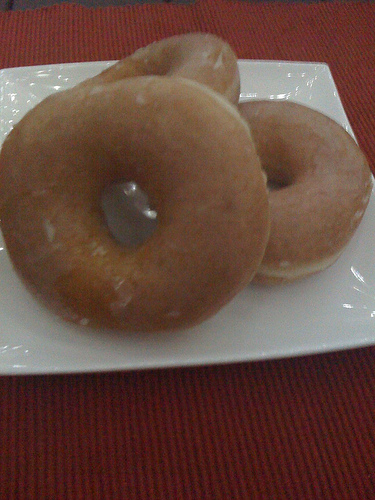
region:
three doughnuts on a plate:
[1, 27, 371, 345]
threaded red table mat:
[5, 1, 95, 56]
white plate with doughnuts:
[17, 323, 302, 387]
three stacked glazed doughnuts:
[1, 30, 364, 325]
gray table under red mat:
[15, 0, 135, 8]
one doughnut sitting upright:
[0, 77, 241, 332]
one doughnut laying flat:
[233, 97, 371, 285]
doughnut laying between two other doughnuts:
[97, 30, 248, 80]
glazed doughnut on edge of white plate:
[267, 87, 370, 284]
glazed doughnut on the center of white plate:
[3, 78, 277, 333]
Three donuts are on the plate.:
[5, 31, 370, 333]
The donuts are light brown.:
[1, 28, 371, 344]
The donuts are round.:
[9, 32, 372, 348]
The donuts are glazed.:
[4, 32, 371, 329]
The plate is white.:
[0, 45, 374, 387]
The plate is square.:
[1, 48, 373, 384]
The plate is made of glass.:
[1, 44, 373, 404]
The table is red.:
[2, 380, 374, 498]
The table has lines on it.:
[150, 387, 367, 492]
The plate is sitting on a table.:
[1, 52, 373, 425]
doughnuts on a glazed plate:
[6, 22, 323, 344]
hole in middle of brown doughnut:
[2, 75, 272, 333]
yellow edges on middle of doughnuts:
[137, 75, 341, 289]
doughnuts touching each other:
[15, 40, 349, 331]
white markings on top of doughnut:
[34, 212, 184, 333]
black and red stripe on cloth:
[17, 15, 142, 39]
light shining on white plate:
[3, 47, 342, 124]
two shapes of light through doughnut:
[107, 166, 170, 241]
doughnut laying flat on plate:
[229, 63, 369, 281]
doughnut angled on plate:
[70, 30, 265, 120]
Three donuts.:
[10, 34, 364, 359]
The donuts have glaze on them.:
[4, 37, 363, 343]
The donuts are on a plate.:
[0, 47, 372, 401]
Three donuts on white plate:
[19, 37, 364, 311]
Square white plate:
[4, 48, 349, 393]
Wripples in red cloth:
[17, 378, 369, 485]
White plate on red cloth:
[7, 52, 368, 389]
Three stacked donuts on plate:
[4, 41, 370, 321]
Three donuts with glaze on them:
[15, 35, 370, 320]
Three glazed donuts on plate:
[19, 38, 372, 317]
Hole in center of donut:
[91, 160, 169, 250]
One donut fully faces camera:
[9, 76, 265, 354]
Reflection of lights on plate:
[3, 72, 76, 132]